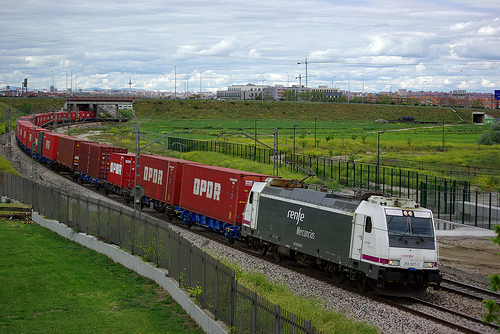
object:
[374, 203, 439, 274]
front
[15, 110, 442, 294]
train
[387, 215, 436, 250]
windshield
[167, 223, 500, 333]
rails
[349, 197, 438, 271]
cabin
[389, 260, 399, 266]
headlight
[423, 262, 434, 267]
headlight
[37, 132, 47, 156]
car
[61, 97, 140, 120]
bridge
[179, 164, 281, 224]
car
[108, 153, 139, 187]
car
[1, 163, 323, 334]
fence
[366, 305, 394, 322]
gravel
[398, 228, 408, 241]
wiper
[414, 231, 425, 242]
wiper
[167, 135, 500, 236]
fence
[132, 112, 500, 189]
grass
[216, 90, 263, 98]
buildings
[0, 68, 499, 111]
background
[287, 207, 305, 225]
lettering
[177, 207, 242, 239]
bottom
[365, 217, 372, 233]
window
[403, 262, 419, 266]
number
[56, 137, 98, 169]
cargo container